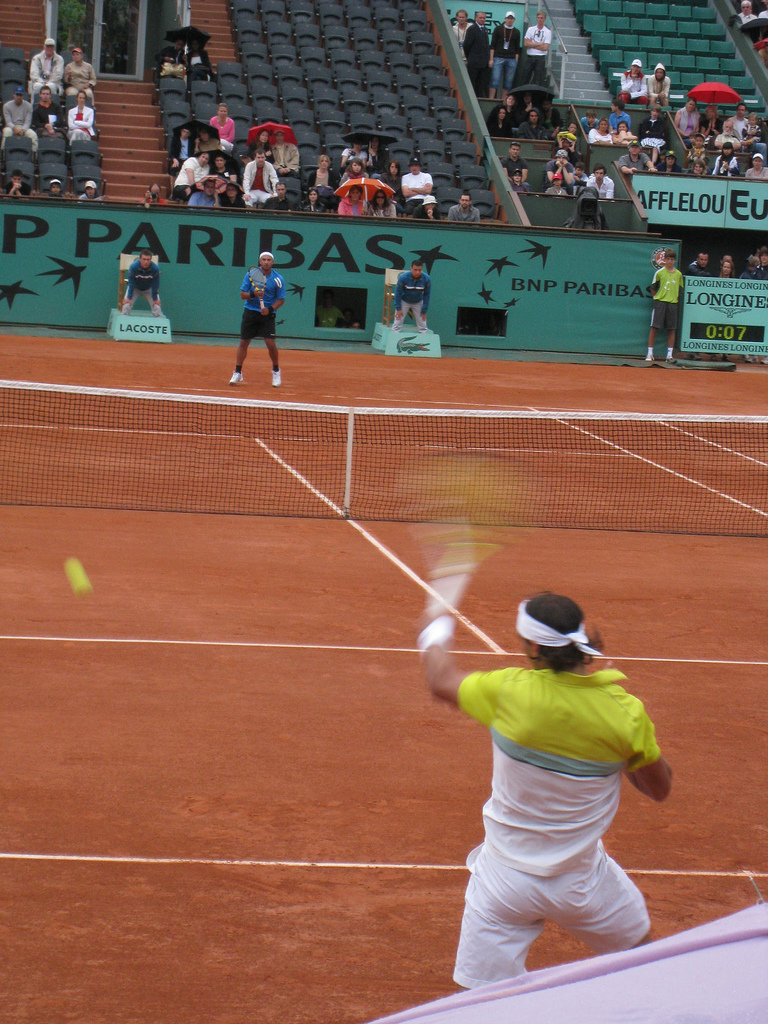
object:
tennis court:
[4, 342, 767, 1023]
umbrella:
[682, 76, 743, 131]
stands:
[539, 2, 765, 186]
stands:
[150, 8, 506, 222]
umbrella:
[327, 173, 398, 205]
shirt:
[239, 255, 286, 320]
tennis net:
[0, 373, 746, 535]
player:
[222, 247, 296, 394]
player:
[414, 588, 682, 1005]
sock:
[232, 362, 243, 373]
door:
[47, 0, 188, 83]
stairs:
[93, 76, 176, 204]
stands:
[0, 2, 506, 223]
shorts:
[237, 309, 284, 342]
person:
[607, 54, 652, 109]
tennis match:
[113, 183, 760, 1021]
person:
[644, 54, 674, 112]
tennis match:
[184, 219, 698, 988]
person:
[582, 159, 621, 209]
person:
[536, 143, 577, 187]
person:
[490, 134, 529, 181]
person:
[669, 98, 710, 153]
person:
[616, 115, 638, 162]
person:
[241, 137, 280, 209]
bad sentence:
[703, 514, 728, 561]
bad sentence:
[720, 561, 750, 605]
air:
[30, 493, 161, 610]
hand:
[412, 583, 456, 657]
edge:
[197, 386, 361, 425]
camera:
[564, 178, 610, 233]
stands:
[536, 156, 639, 232]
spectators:
[336, 183, 397, 216]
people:
[468, 3, 563, 105]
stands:
[450, 0, 634, 145]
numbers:
[699, 315, 765, 347]